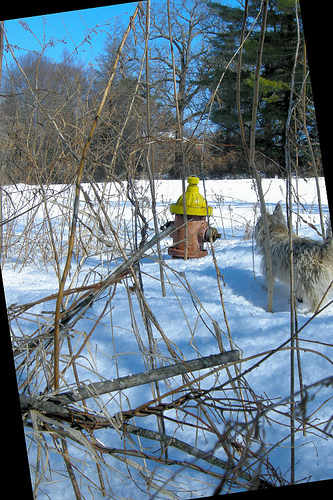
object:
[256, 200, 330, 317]
dog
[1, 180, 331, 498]
snow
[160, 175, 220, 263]
fire hydrant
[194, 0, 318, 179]
pine tree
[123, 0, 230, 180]
tree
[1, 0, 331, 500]
branches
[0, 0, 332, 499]
day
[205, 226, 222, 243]
water outlet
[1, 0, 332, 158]
sky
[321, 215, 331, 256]
tail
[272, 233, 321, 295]
body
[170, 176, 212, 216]
yellow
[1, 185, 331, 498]
ground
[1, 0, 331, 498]
field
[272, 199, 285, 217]
ears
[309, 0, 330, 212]
trees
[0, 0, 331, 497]
twigs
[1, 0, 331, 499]
sunlight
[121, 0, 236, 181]
limbs